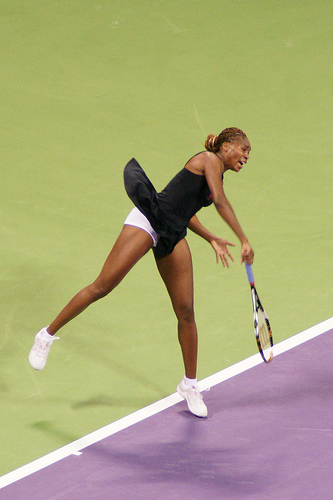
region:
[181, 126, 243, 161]
woman has braided hair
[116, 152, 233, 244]
woman has black dress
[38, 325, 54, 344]
woman has white socks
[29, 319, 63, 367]
woman has white shoes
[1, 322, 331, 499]
white line on court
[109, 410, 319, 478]
court is light purple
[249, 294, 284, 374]
black and orange racket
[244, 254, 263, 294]
blue handle on racket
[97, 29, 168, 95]
green area out of bounds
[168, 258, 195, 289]
the womens thigh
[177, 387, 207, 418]
white shoe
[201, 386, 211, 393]
a white shoe lace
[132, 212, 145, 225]
white shorts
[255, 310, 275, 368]
the tennis racket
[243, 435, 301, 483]
the tennis court is purple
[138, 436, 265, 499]
a shadow on the tennis court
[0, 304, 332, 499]
The line on the tennis court is white.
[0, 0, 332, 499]
The tennis court is green and purple.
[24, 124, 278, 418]
The woman is holding a tennis racket.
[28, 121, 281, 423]
The woman is wearing a tennis dress.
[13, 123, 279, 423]
The woman's hair is braided.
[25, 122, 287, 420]
The woman's right leg is off the ground.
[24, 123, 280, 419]
The woman's tennis dress is sleeveless.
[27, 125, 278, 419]
The woman's tennis dress is black.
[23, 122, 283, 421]
The woman's tennis dress is flipped up in the back.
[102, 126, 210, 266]
this is a dress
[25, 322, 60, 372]
this ia shoe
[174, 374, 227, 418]
this is a shoe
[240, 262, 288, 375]
this is a racket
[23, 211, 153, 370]
this is a leg of a person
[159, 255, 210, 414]
this is a leg of a person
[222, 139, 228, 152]
this is an ear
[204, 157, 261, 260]
this is a hand of a person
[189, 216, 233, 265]
this is a hand of a person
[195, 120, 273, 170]
this is a head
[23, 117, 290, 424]
Woman playing tennis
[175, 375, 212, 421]
White tennis shoe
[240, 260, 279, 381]
A tennis racquet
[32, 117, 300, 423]
Woman holding a tennis racquet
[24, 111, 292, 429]
Woman in black sports outfit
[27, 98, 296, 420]
Woman jumping off ground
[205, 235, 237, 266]
An open hand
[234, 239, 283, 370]
Hand holding a tennis racquet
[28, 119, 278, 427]
A woman in a black dress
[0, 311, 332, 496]
Purple and white section of court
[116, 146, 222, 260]
a black tennis dress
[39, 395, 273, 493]
shadow on the ground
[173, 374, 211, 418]
a white laced shoe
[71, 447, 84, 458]
white paint on the ground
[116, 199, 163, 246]
tennis player's white underwear